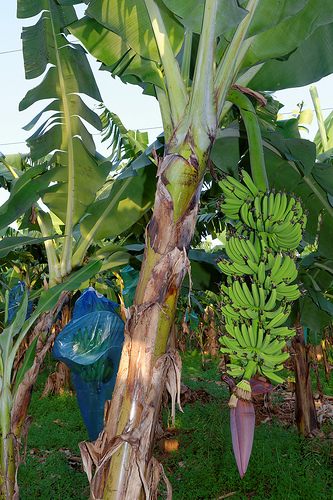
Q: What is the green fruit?
A: Bananas.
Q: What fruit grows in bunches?
A: Bananas.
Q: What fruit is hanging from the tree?
A: Bananas.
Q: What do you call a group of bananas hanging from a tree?
A: A bunch.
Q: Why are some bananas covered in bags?
A: To protect the fruit from insects.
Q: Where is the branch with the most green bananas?
A: On the right side of the photo.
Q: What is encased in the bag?
A: Bananas.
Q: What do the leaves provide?
A: Shade.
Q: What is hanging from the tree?
A: Bananas.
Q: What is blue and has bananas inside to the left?
A: A plastic bag.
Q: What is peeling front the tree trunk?
A: Dried leaves.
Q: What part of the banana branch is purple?
A: The un-bloomed flower.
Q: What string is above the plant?
A: The power line.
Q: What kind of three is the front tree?
A: A banana tree.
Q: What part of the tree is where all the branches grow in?
A: The top middle part of the first tree.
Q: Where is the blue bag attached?
A: The tree.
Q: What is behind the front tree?
A: Trees.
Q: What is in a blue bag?
A: Green bananas.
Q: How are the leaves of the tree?
A: Long.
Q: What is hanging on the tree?
A: Fruit.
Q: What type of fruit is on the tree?
A: Bananas.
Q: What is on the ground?
A: Grass.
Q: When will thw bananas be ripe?
A: When they turn yellow.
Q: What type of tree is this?
A: A fruit bearing tree.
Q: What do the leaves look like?
A: Large.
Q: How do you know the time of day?
A: Because it is light out.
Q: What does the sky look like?
A: Bright and sunny.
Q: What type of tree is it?
A: Banana.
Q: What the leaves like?
A: Long and ribbed.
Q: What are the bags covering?
A: Bananas.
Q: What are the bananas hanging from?
A: Tree.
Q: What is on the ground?
A: Grass.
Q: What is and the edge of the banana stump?
A: Dry Leaf.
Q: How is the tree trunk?
A: Layered in leaves.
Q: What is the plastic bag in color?
A: Blue.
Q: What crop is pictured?
A: Plantains.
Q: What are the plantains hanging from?
A: Tree.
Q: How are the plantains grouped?
A: Bunches.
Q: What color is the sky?
A: Blue.